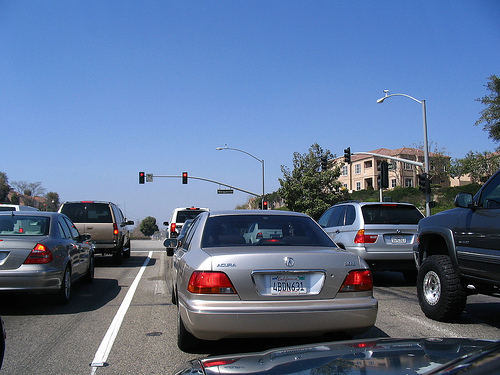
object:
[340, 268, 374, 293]
tail light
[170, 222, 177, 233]
tail light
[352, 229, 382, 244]
tail light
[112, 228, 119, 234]
tail light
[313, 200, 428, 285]
car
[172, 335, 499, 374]
car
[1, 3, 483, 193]
sky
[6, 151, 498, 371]
lanes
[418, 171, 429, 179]
traffic lights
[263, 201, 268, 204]
traffic light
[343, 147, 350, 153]
traffic light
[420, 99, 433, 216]
pole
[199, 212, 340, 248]
window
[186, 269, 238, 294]
light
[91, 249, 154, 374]
white line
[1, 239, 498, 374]
road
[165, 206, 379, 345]
acura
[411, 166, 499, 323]
car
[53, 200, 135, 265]
car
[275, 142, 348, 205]
tree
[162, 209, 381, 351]
car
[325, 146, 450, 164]
roof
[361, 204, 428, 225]
window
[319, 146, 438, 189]
building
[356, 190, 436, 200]
hill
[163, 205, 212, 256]
cars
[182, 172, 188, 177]
light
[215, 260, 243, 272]
wordmark.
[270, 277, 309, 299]
license plate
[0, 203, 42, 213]
car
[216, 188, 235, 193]
sign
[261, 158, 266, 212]
pole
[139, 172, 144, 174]
red light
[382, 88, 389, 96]
camera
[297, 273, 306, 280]
tag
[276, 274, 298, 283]
california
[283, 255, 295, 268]
logo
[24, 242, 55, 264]
light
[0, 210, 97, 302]
car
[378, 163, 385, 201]
pole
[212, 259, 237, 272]
acura wordmark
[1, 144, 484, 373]
traffic